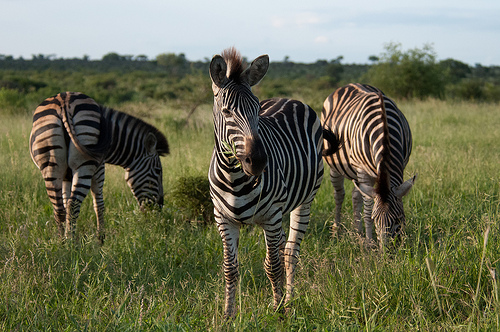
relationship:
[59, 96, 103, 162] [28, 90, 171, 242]
tail on end of zebra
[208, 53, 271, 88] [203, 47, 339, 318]
ears on head of zebra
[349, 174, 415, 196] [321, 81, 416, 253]
ears on top of zebra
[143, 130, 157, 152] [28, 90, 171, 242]
ear on head of zebra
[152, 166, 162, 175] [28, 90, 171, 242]
eye on side of zebra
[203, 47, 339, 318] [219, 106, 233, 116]
zebra has eye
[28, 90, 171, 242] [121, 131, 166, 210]
zebra has head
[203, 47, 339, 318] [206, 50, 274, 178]
zebra has head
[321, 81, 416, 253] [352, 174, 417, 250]
zebra has head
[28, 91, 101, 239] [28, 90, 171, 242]
rear of first zebra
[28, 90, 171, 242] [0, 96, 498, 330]
zebra grazing on grass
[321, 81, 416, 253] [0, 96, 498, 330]
zebra grazing on grass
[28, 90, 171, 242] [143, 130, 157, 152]
zebra has ear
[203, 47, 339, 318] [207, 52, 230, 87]
zebra has ear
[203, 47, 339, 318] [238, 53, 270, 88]
zebra has ears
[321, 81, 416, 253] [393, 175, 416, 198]
zebra has ear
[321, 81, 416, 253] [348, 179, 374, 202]
zebra has ears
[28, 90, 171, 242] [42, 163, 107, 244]
zebra has legs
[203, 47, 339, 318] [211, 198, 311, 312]
zebra has legs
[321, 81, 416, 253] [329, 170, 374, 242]
zebra has legs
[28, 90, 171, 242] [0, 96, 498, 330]
zebra standing in grass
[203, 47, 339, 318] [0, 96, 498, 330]
zebra standing in grass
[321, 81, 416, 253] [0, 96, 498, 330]
zebra standing in grass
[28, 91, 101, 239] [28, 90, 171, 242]
rear of left zebra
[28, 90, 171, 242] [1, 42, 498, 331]
zebra standing in field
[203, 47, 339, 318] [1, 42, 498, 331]
zebra standing in field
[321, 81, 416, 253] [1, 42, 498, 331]
zebra standing in field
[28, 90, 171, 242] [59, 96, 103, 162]
zebra has tail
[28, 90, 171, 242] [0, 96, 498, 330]
zebra eating grass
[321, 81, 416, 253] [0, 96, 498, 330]
zebra eating grass